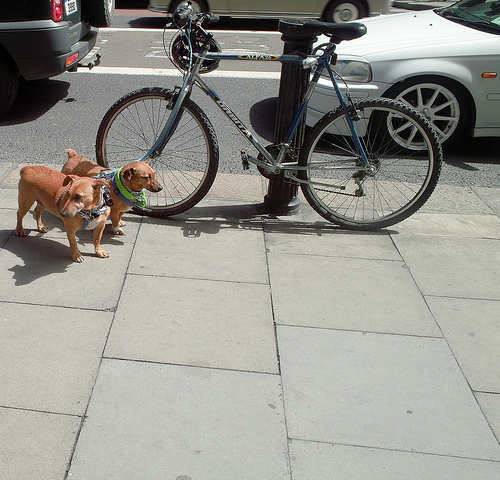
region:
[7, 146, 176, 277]
two small brown dogs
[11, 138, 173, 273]
two dogs standing on the sidewalk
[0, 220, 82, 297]
shadow from the dog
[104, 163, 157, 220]
green and blue collar around the dog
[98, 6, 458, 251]
bike leaning against a short black post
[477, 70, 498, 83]
small orange reflector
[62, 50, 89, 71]
tiny red light on the bottom of the car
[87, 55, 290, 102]
thick white line on the road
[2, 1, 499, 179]
two cars on the road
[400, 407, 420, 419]
small tar mark on the ground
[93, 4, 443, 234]
A bicycle attached to a pole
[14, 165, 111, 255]
A small dog with a blue collar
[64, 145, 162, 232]
A small dog with a green collar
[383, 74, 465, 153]
A tire on a white car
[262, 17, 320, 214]
A black metal pole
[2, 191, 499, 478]
A concrete sidewalk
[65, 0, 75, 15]
A license plate on the back of a car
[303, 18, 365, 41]
A black bike seat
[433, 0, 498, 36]
A windshield on a white car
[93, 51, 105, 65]
A tow hitch on a car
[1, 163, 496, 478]
The sidewalk is gray.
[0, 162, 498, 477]
The sidewalk is made of blocks.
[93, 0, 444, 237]
A bike is in the picture.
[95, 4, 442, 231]
The bike is leaning against a post.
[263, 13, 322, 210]
The post is made of metal.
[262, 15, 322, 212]
The post is black.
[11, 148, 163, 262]
Two dogs are in the picture.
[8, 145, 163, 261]
The dogs are brown.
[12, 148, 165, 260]
The dogs are small.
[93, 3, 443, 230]
The bike is blue.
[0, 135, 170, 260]
Two brown color dogs standing in the street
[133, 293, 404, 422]
White color floor tiles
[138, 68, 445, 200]
A cycle parked near the post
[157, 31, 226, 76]
Black color helmet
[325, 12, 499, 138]
White color car parked near the cycle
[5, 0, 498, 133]
Three cars and one cycle parked in the street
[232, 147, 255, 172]
Pedal of the cycle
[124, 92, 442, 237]
Tyres of the cycle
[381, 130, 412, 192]
Spokes of the cycle wheel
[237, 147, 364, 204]
Cycle chain with pedal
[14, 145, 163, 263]
two small dogs standing on the sidewalk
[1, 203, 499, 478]
a sidewalk next to the street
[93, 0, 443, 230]
a bicycle parked on the sidewalk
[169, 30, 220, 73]
a helmet hanging from the bicycle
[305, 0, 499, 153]
a white car behind the bicycle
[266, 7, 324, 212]
a black post on the sidewalk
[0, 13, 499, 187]
a busy city street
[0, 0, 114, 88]
the back of a car behind the dogs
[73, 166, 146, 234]
brightly-colored collars on dogs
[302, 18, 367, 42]
seat of the bicycle